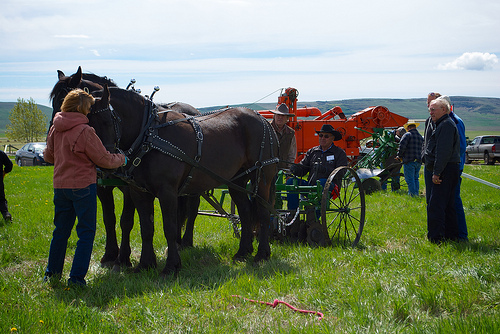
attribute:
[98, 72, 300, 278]
horses — standing, brown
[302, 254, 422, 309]
grass — green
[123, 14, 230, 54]
sky — blue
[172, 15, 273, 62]
clouds — white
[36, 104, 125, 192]
jacket — red, pink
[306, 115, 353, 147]
hat — tan, black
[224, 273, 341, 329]
rope — red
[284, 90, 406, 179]
equipment — red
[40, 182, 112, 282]
jeans — blue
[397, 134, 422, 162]
shirt — plaid